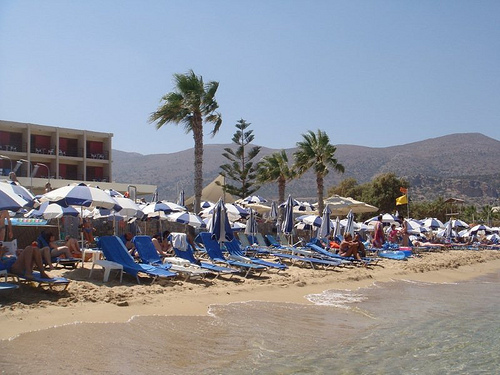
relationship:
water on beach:
[3, 267, 498, 373] [2, 244, 494, 372]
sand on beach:
[0, 251, 497, 341] [2, 244, 494, 372]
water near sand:
[3, 267, 498, 373] [147, 284, 219, 321]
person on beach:
[338, 229, 358, 263] [21, 99, 493, 364]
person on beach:
[371, 210, 384, 246] [21, 99, 493, 364]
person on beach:
[386, 220, 399, 244] [21, 99, 493, 364]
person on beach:
[399, 223, 409, 243] [21, 99, 493, 364]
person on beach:
[353, 229, 366, 260] [21, 99, 493, 364]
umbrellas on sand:
[41, 182, 122, 269] [0, 251, 497, 341]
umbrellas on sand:
[283, 192, 297, 247] [0, 251, 497, 341]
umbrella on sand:
[138, 200, 187, 215] [0, 251, 497, 341]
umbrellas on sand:
[440, 217, 455, 244] [0, 251, 497, 341]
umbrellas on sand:
[165, 210, 205, 236] [0, 251, 497, 341]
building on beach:
[3, 118, 159, 200] [2, 244, 494, 372]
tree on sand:
[150, 68, 222, 218] [1, 246, 498, 373]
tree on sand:
[213, 117, 263, 197] [1, 246, 498, 373]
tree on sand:
[251, 147, 293, 201] [1, 246, 498, 373]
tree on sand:
[285, 129, 344, 215] [1, 246, 498, 373]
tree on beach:
[150, 68, 222, 218] [2, 244, 494, 372]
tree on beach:
[213, 117, 263, 197] [2, 244, 494, 372]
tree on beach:
[251, 147, 293, 201] [2, 244, 494, 372]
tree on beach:
[285, 129, 344, 215] [2, 244, 494, 372]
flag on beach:
[400, 186, 407, 193] [1, 234, 498, 346]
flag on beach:
[393, 191, 412, 208] [1, 234, 498, 346]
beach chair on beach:
[94, 234, 177, 285] [11, 252, 498, 338]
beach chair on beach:
[131, 235, 208, 283] [11, 252, 498, 338]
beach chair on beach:
[167, 232, 238, 281] [11, 252, 498, 338]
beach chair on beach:
[199, 232, 266, 278] [11, 252, 498, 338]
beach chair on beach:
[222, 237, 287, 273] [11, 252, 498, 338]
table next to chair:
[79, 252, 120, 280] [88, 227, 174, 285]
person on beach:
[0, 245, 54, 278] [19, 284, 344, 316]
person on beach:
[31, 232, 87, 262] [19, 284, 344, 316]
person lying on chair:
[43, 229, 83, 262] [26, 229, 86, 269]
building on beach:
[0, 118, 159, 257] [2, 227, 499, 371]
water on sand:
[3, 267, 498, 373] [1, 246, 498, 373]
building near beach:
[0, 118, 159, 257] [9, 185, 491, 319]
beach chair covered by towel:
[94, 234, 177, 285] [95, 232, 162, 274]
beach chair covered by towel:
[131, 235, 208, 283] [135, 234, 185, 268]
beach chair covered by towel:
[167, 232, 238, 281] [171, 246, 221, 271]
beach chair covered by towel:
[199, 232, 266, 278] [197, 229, 226, 262]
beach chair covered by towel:
[222, 237, 287, 273] [220, 238, 248, 256]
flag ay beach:
[395, 183, 412, 221] [37, 239, 488, 354]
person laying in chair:
[0, 250, 64, 288] [24, 266, 69, 284]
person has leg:
[0, 250, 64, 288] [11, 242, 35, 279]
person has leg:
[0, 250, 64, 288] [32, 245, 50, 277]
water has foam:
[3, 267, 498, 373] [1, 275, 499, 345]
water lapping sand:
[3, 267, 498, 373] [1, 246, 498, 373]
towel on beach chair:
[169, 229, 193, 255] [167, 232, 238, 281]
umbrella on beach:
[138, 200, 183, 245] [0, 170, 498, 332]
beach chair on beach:
[131, 235, 208, 283] [2, 244, 494, 372]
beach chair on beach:
[199, 232, 266, 278] [2, 244, 494, 372]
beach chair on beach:
[222, 237, 287, 273] [2, 244, 494, 372]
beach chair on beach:
[270, 253, 343, 271] [2, 244, 494, 372]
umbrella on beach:
[416, 213, 444, 233] [1, 224, 496, 351]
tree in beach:
[289, 121, 351, 186] [8, 185, 498, 370]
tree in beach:
[150, 68, 222, 218] [2, 207, 495, 359]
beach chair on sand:
[275, 249, 337, 266] [140, 282, 210, 314]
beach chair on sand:
[225, 245, 285, 270] [140, 282, 210, 314]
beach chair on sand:
[167, 232, 238, 281] [140, 282, 210, 314]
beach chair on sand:
[131, 235, 208, 283] [140, 282, 210, 314]